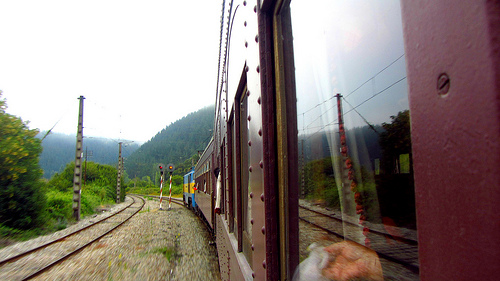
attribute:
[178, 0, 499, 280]
train — red, blue, yellow, burgundy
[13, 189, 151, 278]
tracks — empty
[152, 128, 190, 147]
trees — pine, green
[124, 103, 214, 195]
hills — dark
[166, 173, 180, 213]
pole — red, white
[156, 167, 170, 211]
pole — red, white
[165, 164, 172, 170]
light — on, red, small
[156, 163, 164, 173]
light — on, red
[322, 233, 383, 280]
hand — holding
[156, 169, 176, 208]
poles — red, white, striped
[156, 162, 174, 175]
lights — red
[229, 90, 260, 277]
window — rectangular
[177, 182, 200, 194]
stripe — yellow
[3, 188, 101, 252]
grass — green, bright, growing